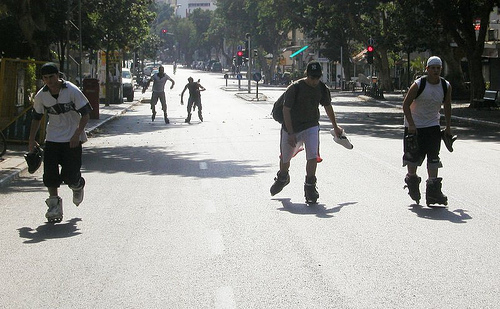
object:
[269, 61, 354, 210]
guy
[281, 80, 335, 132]
shirt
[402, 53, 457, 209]
guy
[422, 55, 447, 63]
hat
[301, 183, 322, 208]
rollerblades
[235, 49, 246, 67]
light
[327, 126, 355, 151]
shoes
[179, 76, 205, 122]
person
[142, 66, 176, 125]
person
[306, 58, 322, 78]
hat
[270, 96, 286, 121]
backback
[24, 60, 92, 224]
man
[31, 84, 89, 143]
shirt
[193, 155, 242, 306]
line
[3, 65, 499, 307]
street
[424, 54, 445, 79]
head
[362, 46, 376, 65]
light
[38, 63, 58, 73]
hat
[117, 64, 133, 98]
vehicle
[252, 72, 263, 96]
sign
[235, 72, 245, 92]
sign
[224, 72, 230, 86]
sign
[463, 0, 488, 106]
tree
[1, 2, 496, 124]
background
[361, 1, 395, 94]
tree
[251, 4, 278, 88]
tree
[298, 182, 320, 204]
feet